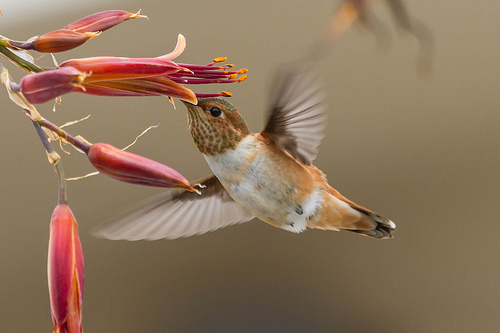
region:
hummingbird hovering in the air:
[93, 77, 402, 267]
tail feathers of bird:
[342, 200, 416, 245]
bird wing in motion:
[262, 43, 339, 147]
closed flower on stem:
[72, 135, 199, 197]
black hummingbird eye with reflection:
[203, 102, 225, 124]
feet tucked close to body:
[280, 200, 309, 234]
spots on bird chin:
[195, 119, 220, 154]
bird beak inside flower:
[160, 77, 195, 109]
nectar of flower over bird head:
[167, 62, 232, 102]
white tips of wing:
[131, 225, 209, 255]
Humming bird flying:
[90, 62, 407, 254]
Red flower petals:
[18, 194, 112, 330]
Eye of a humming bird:
[196, 100, 235, 128]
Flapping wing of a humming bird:
[266, 37, 348, 154]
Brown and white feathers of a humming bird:
[209, 133, 399, 240]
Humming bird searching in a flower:
[66, 49, 273, 150]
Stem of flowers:
[16, 108, 105, 208]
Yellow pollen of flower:
[187, 43, 259, 99]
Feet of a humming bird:
[269, 188, 319, 232]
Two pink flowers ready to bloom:
[13, 2, 165, 55]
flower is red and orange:
[70, 142, 262, 227]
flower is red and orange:
[53, 119, 178, 188]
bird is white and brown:
[84, 89, 481, 276]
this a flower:
[48, 51, 230, 91]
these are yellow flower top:
[206, 53, 258, 100]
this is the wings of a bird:
[87, 170, 244, 247]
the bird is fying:
[162, 47, 381, 243]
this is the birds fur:
[236, 142, 308, 201]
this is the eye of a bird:
[204, 100, 224, 130]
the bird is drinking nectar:
[166, 83, 226, 141]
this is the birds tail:
[313, 172, 410, 256]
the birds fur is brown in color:
[245, 151, 373, 241]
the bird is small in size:
[129, 65, 394, 252]